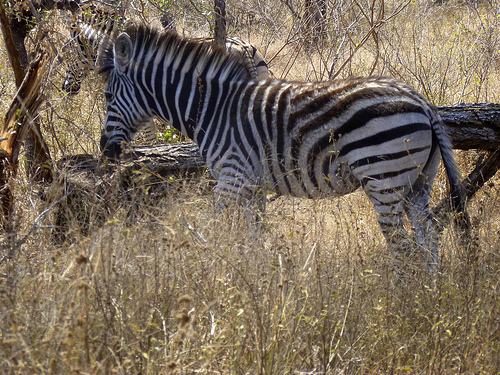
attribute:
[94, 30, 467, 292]
zebra — black, white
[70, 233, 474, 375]
grass — brown, tall, dry, long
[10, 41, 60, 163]
branch — brown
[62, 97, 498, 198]
log — gray, dead, dry